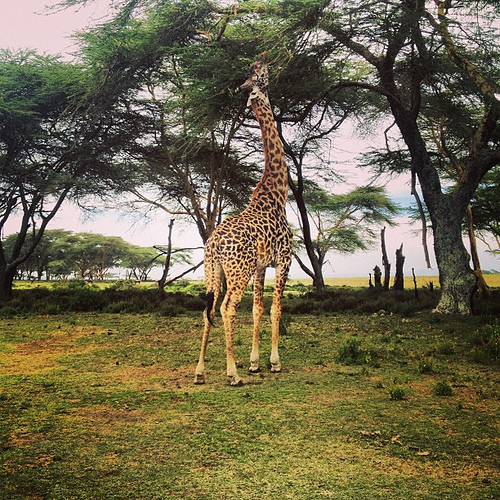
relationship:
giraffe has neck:
[183, 81, 330, 395] [247, 104, 299, 209]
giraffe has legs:
[183, 81, 330, 395] [193, 272, 303, 385]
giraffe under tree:
[183, 81, 330, 395] [4, 50, 147, 310]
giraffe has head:
[183, 81, 330, 395] [227, 85, 290, 139]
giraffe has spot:
[183, 81, 330, 395] [256, 228, 277, 242]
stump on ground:
[365, 242, 408, 303] [41, 318, 498, 482]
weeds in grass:
[337, 326, 369, 366] [30, 311, 493, 484]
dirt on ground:
[25, 319, 80, 367] [41, 318, 498, 482]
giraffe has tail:
[183, 81, 330, 395] [193, 264, 227, 334]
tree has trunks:
[4, 50, 147, 310] [350, 236, 415, 303]